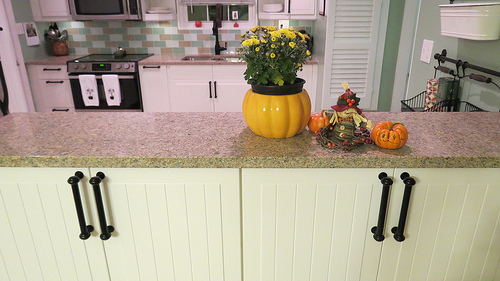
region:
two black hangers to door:
[58, 163, 116, 242]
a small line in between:
[221, 174, 259, 279]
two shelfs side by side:
[6, 170, 498, 280]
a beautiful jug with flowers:
[200, 27, 323, 136]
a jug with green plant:
[226, 6, 315, 153]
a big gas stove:
[68, 52, 157, 119]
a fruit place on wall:
[361, 107, 426, 155]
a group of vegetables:
[314, 77, 431, 172]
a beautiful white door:
[326, 12, 388, 114]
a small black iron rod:
[410, 42, 499, 78]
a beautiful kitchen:
[1, 12, 499, 279]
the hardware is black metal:
[367, 170, 418, 265]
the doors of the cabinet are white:
[255, 166, 370, 273]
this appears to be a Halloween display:
[220, 7, 423, 145]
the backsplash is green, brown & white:
[76, 25, 197, 56]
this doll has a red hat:
[330, 75, 380, 145]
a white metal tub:
[425, 0, 497, 45]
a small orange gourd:
[366, 115, 409, 152]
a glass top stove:
[47, 42, 154, 82]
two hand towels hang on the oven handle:
[76, 70, 132, 113]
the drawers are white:
[170, 194, 306, 251]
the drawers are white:
[188, 215, 304, 265]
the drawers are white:
[58, 226, 185, 271]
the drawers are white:
[163, 195, 428, 275]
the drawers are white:
[246, 212, 362, 272]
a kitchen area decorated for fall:
[0, 7, 493, 244]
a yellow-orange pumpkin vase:
[231, 22, 312, 148]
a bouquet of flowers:
[233, 16, 312, 79]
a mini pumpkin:
[368, 117, 413, 157]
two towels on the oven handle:
[63, 70, 132, 112]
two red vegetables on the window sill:
[190, 16, 252, 31]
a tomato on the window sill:
[186, 15, 208, 30]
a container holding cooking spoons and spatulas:
[44, 21, 72, 58]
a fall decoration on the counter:
[311, 82, 371, 154]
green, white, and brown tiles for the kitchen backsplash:
[46, 15, 229, 57]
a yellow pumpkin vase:
[226, 34, 427, 202]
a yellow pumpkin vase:
[222, 72, 377, 247]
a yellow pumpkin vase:
[264, 68, 359, 149]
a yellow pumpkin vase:
[227, 44, 327, 184]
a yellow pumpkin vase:
[178, 78, 307, 200]